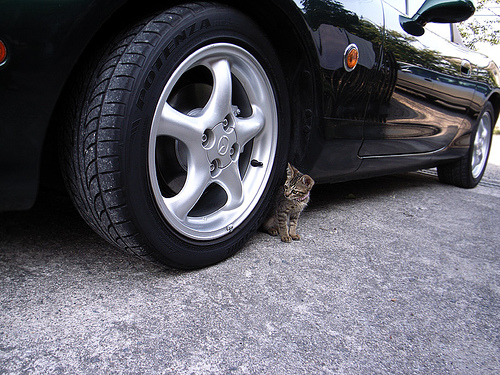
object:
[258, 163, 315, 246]
kitten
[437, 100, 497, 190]
tire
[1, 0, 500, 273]
car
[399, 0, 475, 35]
mirror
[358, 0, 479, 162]
door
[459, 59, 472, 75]
handle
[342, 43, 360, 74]
reflector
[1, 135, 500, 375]
ground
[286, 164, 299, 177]
ear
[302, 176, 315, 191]
ear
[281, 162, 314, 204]
head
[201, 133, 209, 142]
lug nut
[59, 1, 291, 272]
wheel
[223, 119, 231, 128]
lug nut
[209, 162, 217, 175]
lug nut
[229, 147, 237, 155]
lug nut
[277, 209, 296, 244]
leg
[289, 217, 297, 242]
leg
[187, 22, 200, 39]
z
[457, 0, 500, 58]
sky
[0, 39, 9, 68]
light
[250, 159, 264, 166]
air valve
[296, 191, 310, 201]
collar